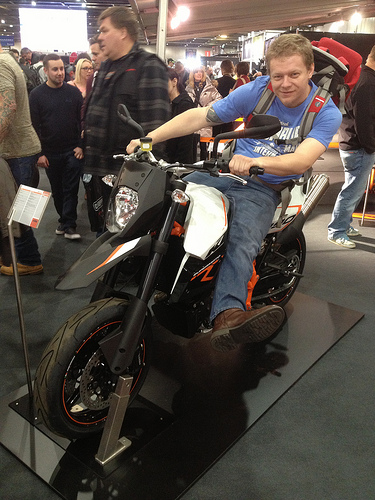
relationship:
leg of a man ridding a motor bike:
[221, 256, 262, 331] [35, 301, 240, 487]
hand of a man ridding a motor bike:
[236, 142, 319, 174] [53, 256, 278, 469]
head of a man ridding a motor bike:
[251, 77, 304, 130] [57, 265, 273, 438]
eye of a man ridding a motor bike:
[290, 61, 302, 101] [88, 320, 266, 456]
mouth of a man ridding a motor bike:
[250, 75, 309, 158] [51, 310, 235, 438]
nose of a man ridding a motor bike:
[259, 66, 297, 115] [41, 321, 201, 437]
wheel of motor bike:
[73, 349, 118, 451] [36, 234, 263, 418]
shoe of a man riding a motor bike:
[214, 301, 280, 389] [43, 305, 235, 476]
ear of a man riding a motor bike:
[306, 88, 320, 127] [64, 200, 308, 317]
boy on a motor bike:
[124, 31, 342, 359] [63, 243, 270, 466]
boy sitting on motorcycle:
[124, 31, 342, 359] [56, 276, 256, 426]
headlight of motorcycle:
[104, 184, 140, 232] [59, 279, 269, 441]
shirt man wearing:
[211, 73, 339, 190] [180, 91, 325, 234]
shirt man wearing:
[240, 109, 312, 197] [165, 59, 360, 168]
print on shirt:
[252, 123, 293, 182] [208, 94, 345, 162]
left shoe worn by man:
[171, 292, 281, 330] [182, 83, 325, 202]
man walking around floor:
[25, 41, 71, 201] [0, 373, 359, 500]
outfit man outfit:
[49, 95, 91, 178] [30, 80, 84, 229]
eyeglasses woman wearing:
[58, 76, 92, 109] [79, 46, 102, 97]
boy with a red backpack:
[153, 75, 370, 300] [341, 37, 358, 105]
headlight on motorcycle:
[110, 181, 141, 232] [26, 100, 311, 444]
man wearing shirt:
[72, 5, 175, 235] [78, 46, 169, 174]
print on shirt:
[254, 123, 303, 159] [209, 74, 345, 189]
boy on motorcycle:
[124, 31, 342, 359] [26, 100, 311, 444]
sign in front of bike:
[7, 183, 51, 230] [27, 99, 308, 448]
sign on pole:
[5, 177, 51, 230] [4, 221, 49, 419]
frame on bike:
[114, 241, 169, 367] [27, 99, 308, 448]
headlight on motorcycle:
[104, 184, 140, 232] [26, 100, 311, 444]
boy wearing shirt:
[124, 31, 342, 359] [209, 74, 345, 189]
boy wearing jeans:
[124, 31, 342, 359] [179, 162, 277, 321]